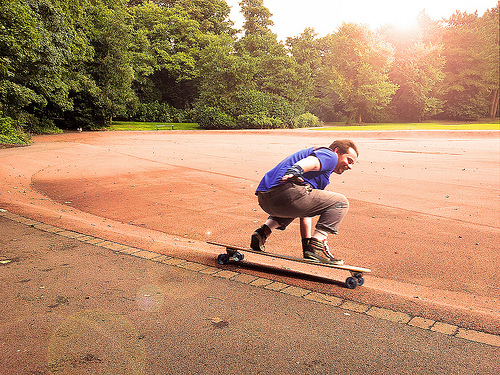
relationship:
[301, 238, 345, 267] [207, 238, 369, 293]
big boot on top of skateboard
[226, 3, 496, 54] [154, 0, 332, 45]
sky behind trees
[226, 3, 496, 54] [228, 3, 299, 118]
sky behind tree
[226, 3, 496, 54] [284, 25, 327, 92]
sky behind tree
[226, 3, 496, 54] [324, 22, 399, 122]
sky behind tree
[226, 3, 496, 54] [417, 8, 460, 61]
sky behind tree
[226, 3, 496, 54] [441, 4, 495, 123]
sky behind tree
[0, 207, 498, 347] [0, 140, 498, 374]
bricks are bording sidewalk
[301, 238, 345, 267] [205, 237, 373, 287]
big boot on skate board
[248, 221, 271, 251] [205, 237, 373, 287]
boot on skate board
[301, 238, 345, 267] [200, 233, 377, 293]
big boot on skateboard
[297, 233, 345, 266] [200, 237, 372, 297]
big boot on skateboard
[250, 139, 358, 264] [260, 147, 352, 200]
man wearing shirt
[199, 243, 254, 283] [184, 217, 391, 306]
wheels on skateboard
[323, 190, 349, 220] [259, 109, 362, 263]
knee on man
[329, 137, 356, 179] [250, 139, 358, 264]
head on man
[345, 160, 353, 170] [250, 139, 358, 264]
nose on man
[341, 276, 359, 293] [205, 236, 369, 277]
wheel of the skateboard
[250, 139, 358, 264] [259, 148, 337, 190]
man in a shirt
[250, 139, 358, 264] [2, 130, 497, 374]
man skateboarding down the street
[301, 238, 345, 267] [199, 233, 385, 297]
big boot on top of a skateboard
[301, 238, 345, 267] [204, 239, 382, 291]
big boot on top of a skate board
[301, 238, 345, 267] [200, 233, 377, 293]
big boot on top of a skateboard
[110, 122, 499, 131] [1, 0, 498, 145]
lawn next to forest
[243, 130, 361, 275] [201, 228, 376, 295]
man on a skateboard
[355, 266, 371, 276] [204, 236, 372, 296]
nose of a skate board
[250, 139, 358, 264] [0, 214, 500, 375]
man skateboarding on sidewalk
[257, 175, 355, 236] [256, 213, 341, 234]
pants with cuffs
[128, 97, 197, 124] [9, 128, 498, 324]
brush on edge of road